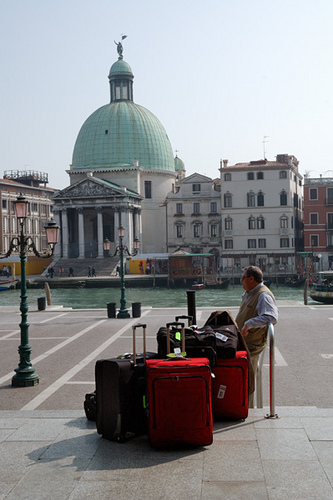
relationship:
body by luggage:
[234, 265, 278, 408] [84, 312, 253, 451]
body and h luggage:
[234, 265, 278, 408] [84, 312, 253, 451]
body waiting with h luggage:
[234, 265, 278, 408] [141, 352, 216, 456]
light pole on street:
[1, 189, 53, 384] [7, 302, 332, 409]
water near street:
[3, 283, 316, 306] [7, 302, 332, 409]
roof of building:
[78, 42, 181, 170] [40, 32, 301, 287]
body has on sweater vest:
[234, 265, 278, 408] [234, 283, 274, 353]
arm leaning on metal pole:
[244, 294, 278, 331] [267, 323, 274, 415]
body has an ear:
[234, 265, 278, 408] [246, 273, 260, 288]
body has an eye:
[234, 265, 278, 408] [241, 275, 247, 281]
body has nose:
[234, 265, 278, 408] [241, 280, 246, 282]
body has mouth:
[234, 265, 278, 408] [241, 283, 247, 288]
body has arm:
[234, 265, 278, 408] [241, 290, 276, 330]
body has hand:
[234, 265, 278, 408] [238, 321, 253, 340]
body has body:
[234, 265, 278, 408] [225, 280, 278, 347]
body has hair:
[234, 265, 278, 408] [244, 265, 264, 281]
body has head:
[234, 265, 278, 408] [239, 264, 262, 289]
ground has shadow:
[190, 453, 323, 496] [25, 432, 208, 473]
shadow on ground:
[25, 432, 208, 473] [190, 453, 323, 496]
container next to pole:
[105, 302, 117, 318] [118, 237, 125, 308]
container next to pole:
[131, 302, 140, 317] [118, 237, 125, 308]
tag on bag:
[217, 384, 226, 399] [211, 350, 249, 422]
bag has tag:
[211, 350, 249, 422] [217, 384, 226, 399]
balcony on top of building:
[1, 167, 48, 181] [0, 177, 60, 261]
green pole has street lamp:
[11, 236, 40, 388] [100, 224, 141, 317]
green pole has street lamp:
[11, 236, 40, 388] [0, 188, 62, 389]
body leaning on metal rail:
[234, 265, 278, 408] [267, 323, 276, 415]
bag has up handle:
[144, 322, 215, 448] [166, 322, 184, 355]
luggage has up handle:
[93, 349, 148, 443] [166, 322, 184, 355]